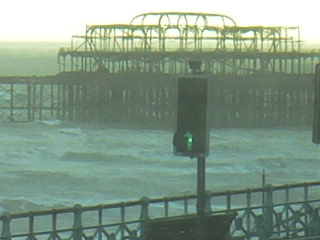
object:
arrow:
[183, 129, 194, 152]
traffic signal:
[170, 74, 209, 239]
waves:
[32, 127, 142, 193]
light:
[167, 72, 212, 160]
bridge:
[1, 10, 320, 129]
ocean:
[0, 113, 320, 239]